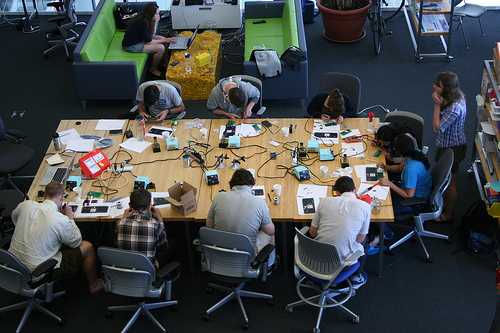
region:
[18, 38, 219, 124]
a person looking down at the table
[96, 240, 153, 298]
the back of a chair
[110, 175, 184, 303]
a person sitting on a chair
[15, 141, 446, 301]
a group of people sitting at a table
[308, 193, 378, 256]
wearing a white shirt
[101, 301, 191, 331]
legs of the chair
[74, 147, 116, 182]
an orange box on the table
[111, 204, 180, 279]
man is wearing checked shirt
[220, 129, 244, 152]
a blue box on the table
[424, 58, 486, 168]
a woman standing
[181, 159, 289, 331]
a man sitting on a chair.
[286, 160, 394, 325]
a person hunched over in a chair.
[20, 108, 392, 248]
a wood table with clutter on it.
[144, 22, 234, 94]
a table between two couch.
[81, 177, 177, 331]
a plaid shirt at a table.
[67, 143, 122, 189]
a folder on a table.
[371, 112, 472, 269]
A kid sitting at a table.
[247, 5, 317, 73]
a green bench near a table.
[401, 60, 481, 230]
a woman standing.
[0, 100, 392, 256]
a table covered in clutter.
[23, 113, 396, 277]
a group of rectangular tables put together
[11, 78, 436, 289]
a group of people sitting at the tables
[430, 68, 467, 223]
a woman standing next to the tables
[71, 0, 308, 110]
two green and blue couches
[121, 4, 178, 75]
a woman sitting on the couch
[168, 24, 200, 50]
an open laptop computer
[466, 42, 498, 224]
a shelf unit to the right of the table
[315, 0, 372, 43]
a large planter next to the couches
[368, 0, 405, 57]
a parked bicycle next to the planter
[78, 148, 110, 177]
a plastic red object on the table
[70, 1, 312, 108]
Two gray and green couches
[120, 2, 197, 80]
A person sitting on a couch using their laptop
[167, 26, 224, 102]
A bright yellow patterned coffee table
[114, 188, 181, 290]
A person with dark hair and brown flannel shirt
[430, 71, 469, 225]
A person with a blue checkered shirt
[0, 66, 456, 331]
A wooden table with people seated around it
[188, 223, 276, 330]
A gray and black rolling chair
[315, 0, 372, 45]
A big red pot for an indoor plant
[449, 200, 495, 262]
A black and blue backpack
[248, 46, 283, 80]
Part of a backpack draped over the end of the couch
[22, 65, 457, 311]
people sitting around large table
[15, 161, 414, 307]
people sitting in row along wooden table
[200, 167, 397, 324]
workers sitting in swivel chairs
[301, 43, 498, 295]
woman supervising seated workers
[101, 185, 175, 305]
boy in plaid shirt sitting at table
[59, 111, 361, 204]
cords and wires strewn across table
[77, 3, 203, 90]
woman sitting on gray and green couch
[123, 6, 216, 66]
woman working on laptop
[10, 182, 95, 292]
man in white shirt and shorts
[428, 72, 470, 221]
girl wearing plaid shirt